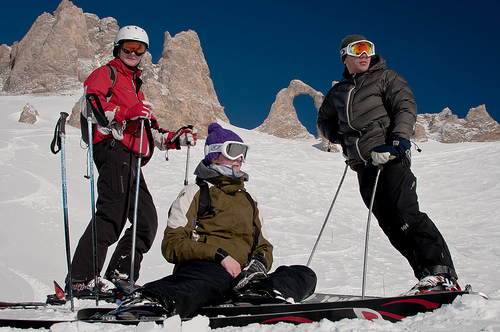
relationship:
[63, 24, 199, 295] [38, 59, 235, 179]
man wears jacket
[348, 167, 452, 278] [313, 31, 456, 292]
pants of man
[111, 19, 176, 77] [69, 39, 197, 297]
helmet of person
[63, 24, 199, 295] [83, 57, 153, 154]
man with jacket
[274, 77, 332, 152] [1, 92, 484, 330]
archway in snow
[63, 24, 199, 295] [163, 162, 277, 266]
man in jacket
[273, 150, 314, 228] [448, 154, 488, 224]
ground in snow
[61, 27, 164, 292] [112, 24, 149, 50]
man in helmet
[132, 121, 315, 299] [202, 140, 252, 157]
man wearing goggles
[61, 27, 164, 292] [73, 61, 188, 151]
man wearing jacket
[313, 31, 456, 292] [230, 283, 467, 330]
man on ski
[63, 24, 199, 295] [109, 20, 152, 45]
man wearing helmet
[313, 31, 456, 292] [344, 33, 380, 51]
man wearing goggles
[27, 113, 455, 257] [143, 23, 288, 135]
snow covering mountain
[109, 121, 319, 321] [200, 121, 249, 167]
man wearing purple hat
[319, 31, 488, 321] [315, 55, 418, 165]
man wearing jacket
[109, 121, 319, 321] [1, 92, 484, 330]
man sitting on snow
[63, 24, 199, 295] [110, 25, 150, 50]
man wearing helmet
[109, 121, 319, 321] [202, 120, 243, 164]
man wearing beanie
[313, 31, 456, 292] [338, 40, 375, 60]
man wearing goggles